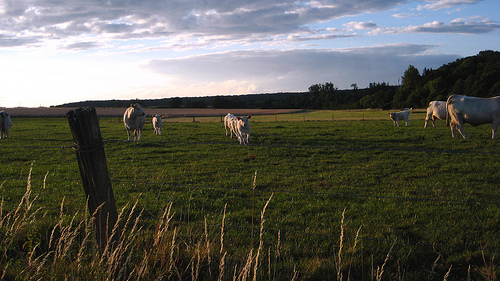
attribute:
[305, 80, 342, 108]
tree — behind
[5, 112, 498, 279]
grass — field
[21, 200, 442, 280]
yellow weeds — tall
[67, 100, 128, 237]
post — hedge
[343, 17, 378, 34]
cloud — white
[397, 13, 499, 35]
cloud — white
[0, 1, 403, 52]
cloud — white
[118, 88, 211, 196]
cow — white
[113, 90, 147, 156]
cow — white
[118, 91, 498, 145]
cattle herd — walking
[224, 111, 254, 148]
calf — running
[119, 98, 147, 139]
sheep — white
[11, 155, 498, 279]
plants — brown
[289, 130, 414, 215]
grass — green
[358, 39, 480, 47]
sky — blue, behind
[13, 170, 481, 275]
grass — tall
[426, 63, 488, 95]
bush — green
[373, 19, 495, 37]
cloud — dark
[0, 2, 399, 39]
cloud — dark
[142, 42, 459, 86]
cloud — dark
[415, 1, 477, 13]
cloud — dark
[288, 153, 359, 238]
grass — green, short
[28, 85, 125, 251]
post — single, wooden